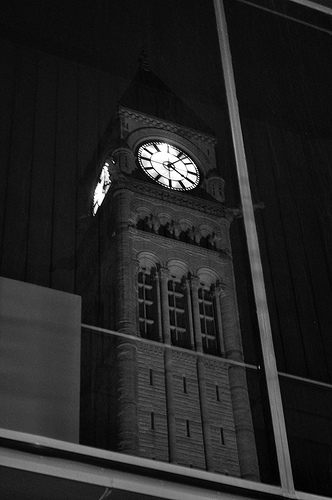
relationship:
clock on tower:
[137, 133, 207, 198] [81, 48, 242, 470]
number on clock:
[163, 141, 171, 155] [137, 133, 207, 198]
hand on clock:
[173, 164, 185, 178] [137, 133, 207, 198]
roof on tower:
[118, 55, 217, 135] [81, 48, 242, 470]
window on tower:
[136, 243, 163, 346] [81, 48, 242, 470]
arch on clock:
[133, 205, 156, 238] [137, 133, 207, 198]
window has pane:
[136, 243, 163, 346] [145, 271, 154, 284]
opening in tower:
[197, 226, 218, 247] [81, 48, 242, 470]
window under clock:
[136, 243, 163, 346] [137, 133, 207, 198]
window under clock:
[167, 265, 194, 355] [137, 133, 207, 198]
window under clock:
[197, 278, 223, 355] [137, 133, 207, 198]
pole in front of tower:
[213, 7, 273, 330] [81, 48, 242, 470]